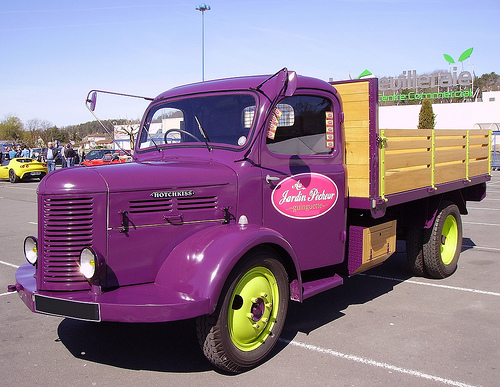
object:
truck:
[6, 68, 491, 375]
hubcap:
[229, 267, 278, 361]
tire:
[198, 252, 293, 376]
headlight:
[21, 234, 41, 264]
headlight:
[78, 245, 97, 279]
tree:
[1, 115, 25, 142]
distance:
[0, 98, 139, 146]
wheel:
[163, 126, 200, 145]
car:
[0, 155, 46, 185]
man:
[43, 141, 56, 172]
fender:
[153, 220, 301, 295]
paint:
[17, 70, 349, 323]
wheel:
[424, 202, 462, 279]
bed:
[378, 125, 492, 197]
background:
[1, 114, 137, 182]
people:
[65, 145, 75, 166]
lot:
[0, 143, 499, 385]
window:
[266, 91, 335, 156]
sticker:
[327, 141, 334, 148]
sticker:
[327, 134, 334, 141]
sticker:
[325, 111, 332, 118]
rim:
[23, 236, 30, 264]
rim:
[24, 262, 36, 266]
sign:
[378, 91, 474, 102]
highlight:
[457, 47, 473, 63]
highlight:
[443, 53, 455, 63]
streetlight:
[192, 3, 211, 84]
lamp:
[195, 5, 211, 12]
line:
[281, 335, 477, 386]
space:
[279, 271, 496, 385]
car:
[81, 149, 132, 166]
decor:
[112, 155, 122, 163]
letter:
[279, 189, 289, 205]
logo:
[270, 170, 340, 220]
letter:
[286, 196, 291, 203]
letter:
[308, 188, 319, 202]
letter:
[408, 90, 414, 101]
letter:
[432, 91, 442, 99]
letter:
[387, 94, 394, 102]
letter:
[154, 193, 160, 198]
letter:
[167, 192, 172, 198]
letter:
[184, 190, 188, 196]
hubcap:
[439, 217, 456, 266]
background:
[376, 66, 497, 130]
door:
[90, 157, 241, 230]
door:
[258, 87, 346, 270]